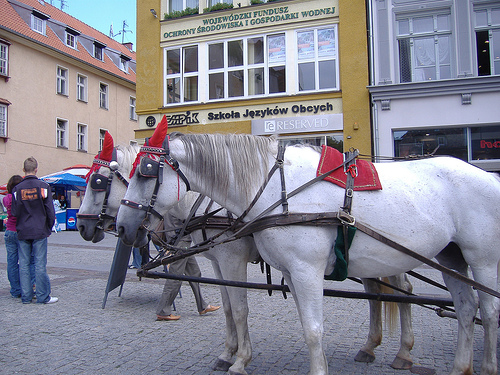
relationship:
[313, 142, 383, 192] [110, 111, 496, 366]
blanket on horse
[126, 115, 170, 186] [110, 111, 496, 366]
tassel on horse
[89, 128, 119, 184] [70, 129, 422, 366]
tassel on horse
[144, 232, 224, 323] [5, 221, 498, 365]
man on sidewalk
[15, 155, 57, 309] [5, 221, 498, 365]
man on sidewalk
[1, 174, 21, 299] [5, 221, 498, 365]
woman on sidewalk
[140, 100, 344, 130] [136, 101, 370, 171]
advertisement on storefront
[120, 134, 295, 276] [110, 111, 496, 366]
bridle on horse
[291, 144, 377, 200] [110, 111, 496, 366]
reins on horse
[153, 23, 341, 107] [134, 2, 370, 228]
window in building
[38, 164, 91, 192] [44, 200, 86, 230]
umbrella over concessions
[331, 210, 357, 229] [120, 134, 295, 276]
buckle on bridle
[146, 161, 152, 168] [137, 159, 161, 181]
button on eye covering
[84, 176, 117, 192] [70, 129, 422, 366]
blinder on horse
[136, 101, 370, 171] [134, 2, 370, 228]
storefront on building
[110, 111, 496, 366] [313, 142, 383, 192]
horse has blanket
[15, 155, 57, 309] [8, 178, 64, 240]
man wearing jacket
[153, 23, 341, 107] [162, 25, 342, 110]
window has frame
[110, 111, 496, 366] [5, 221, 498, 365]
horse standing on sidewalk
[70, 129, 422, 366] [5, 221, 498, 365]
horse standing on sidewalk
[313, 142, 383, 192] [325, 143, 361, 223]
blanket under girth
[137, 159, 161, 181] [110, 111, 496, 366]
eye covering on horse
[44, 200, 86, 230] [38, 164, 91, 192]
concessions with umbrella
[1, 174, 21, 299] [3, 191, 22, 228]
woman dressed in pink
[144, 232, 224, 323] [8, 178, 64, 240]
man dressed in jacket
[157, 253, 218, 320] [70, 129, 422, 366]
person by horse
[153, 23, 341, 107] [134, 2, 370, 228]
window on building